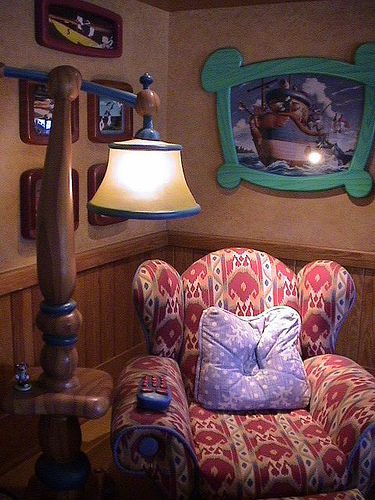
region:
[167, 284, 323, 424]
a light purple pillow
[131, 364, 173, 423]
a TV remote control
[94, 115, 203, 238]
a hanging lampshade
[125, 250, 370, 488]
a large plush armchair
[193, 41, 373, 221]
a picture of a boat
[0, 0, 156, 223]
a collection of pictures on a wall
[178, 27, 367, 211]
a light green frame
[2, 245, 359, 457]
a section of wood paneling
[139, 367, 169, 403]
remote control on the chair's arm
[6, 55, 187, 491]
light fixture beside the chair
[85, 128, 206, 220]
lampshade on the light fixture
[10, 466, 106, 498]
base of the light fixture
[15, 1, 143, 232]
pictures with mahogany wood frames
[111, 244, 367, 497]
patterned chair in the corner of the room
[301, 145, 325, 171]
light reflected on picture frame glass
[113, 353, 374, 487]
arms of the chair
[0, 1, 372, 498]
corner of room with chair and lamp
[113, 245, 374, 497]
chair with pillow against back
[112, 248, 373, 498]
chair with remote control on top of arm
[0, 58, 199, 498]
glowing lamp with white shade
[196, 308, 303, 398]
purple pillow on the chair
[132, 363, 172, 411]
remote control on the chair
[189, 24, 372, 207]
picture on the wall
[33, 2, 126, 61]
picture on the wall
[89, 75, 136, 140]
picture on the wall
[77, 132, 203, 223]
lampshade on the table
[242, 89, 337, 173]
boat in the picture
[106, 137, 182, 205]
The lamp shade is white.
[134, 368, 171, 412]
A remote control on the arm of the chair.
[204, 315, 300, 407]
A pillow sitting on the chair.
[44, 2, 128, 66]
A picture on the wall.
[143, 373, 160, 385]
The remote control has red buttons.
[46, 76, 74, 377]
The lamp pole is wooden.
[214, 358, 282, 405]
The pillow has white dots.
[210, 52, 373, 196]
The picture fram is green.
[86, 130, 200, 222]
A lampshade in the room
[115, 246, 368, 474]
A colorful comfy chair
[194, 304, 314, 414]
a purple pillow on the chair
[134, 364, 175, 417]
TV controller on the arm of the chair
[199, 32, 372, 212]
A picture with an Aqua frame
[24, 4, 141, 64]
A picture on the wall with a brown wooden frame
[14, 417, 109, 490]
The wooden base of a lamp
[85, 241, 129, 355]
Wooden paneling on the wall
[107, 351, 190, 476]
the arm of a comfortable chair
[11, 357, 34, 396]
a figurine on the table stand